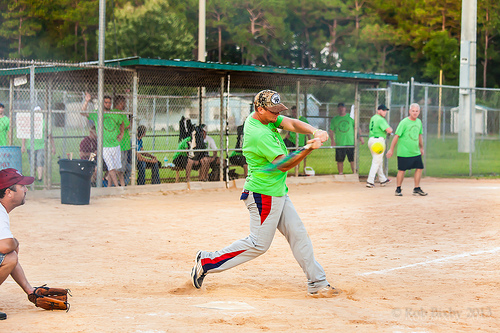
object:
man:
[178, 79, 344, 307]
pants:
[181, 77, 349, 301]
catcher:
[1, 166, 54, 321]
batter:
[176, 83, 338, 299]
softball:
[367, 139, 386, 152]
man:
[2, 167, 44, 314]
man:
[385, 103, 425, 197]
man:
[326, 102, 366, 175]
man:
[367, 101, 397, 190]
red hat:
[0, 165, 35, 188]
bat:
[276, 142, 310, 172]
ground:
[438, 125, 470, 172]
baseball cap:
[253, 90, 286, 111]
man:
[190, 87, 350, 297]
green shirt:
[241, 110, 290, 197]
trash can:
[57, 158, 96, 204]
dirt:
[0, 178, 499, 332]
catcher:
[4, 168, 77, 323]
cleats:
[178, 245, 356, 301]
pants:
[201, 190, 331, 293]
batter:
[190, 87, 346, 298]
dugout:
[74, 72, 351, 176]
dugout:
[133, 61, 225, 152]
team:
[91, 95, 416, 175]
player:
[86, 90, 131, 181]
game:
[11, 120, 380, 312]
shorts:
[382, 148, 435, 173]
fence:
[1, 57, 498, 187]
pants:
[201, 181, 331, 288]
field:
[0, 144, 497, 327]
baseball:
[364, 138, 386, 155]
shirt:
[241, 110, 292, 196]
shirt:
[83, 109, 130, 147]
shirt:
[328, 112, 358, 148]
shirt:
[366, 112, 390, 141]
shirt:
[391, 114, 428, 156]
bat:
[261, 142, 320, 173]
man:
[378, 98, 429, 195]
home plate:
[192, 292, 255, 313]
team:
[80, 83, 446, 307]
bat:
[269, 143, 320, 172]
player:
[184, 82, 348, 295]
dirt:
[117, 195, 422, 325]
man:
[173, 84, 351, 295]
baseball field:
[4, 179, 499, 329]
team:
[81, 87, 445, 297]